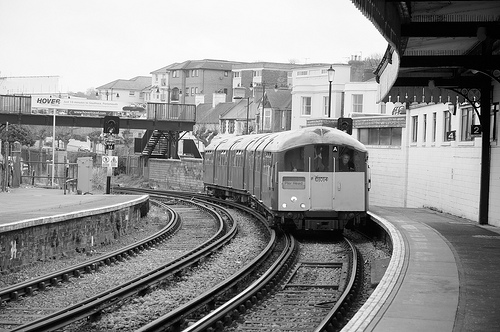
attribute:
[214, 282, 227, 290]
rails — steel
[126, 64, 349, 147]
lights — street 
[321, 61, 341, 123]
lamp post — tall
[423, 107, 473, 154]
sign — information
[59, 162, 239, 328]
tracks — empty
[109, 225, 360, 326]
train tracks — parallel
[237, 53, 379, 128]
lights — street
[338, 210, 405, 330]
line — painted